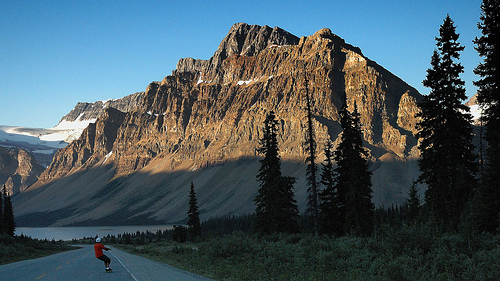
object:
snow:
[10, 118, 82, 151]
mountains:
[77, 29, 381, 176]